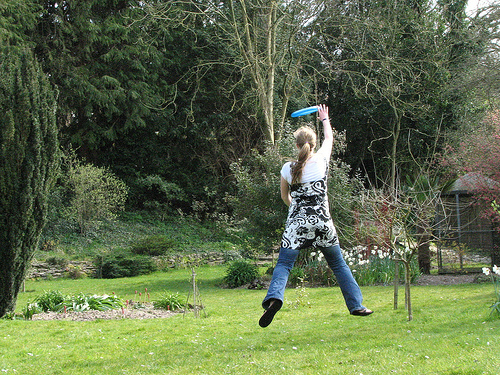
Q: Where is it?
A: This is at the field.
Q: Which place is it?
A: It is a field.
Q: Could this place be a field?
A: Yes, it is a field.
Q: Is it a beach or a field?
A: It is a field.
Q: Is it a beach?
A: No, it is a field.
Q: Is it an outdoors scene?
A: Yes, it is outdoors.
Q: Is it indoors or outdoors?
A: It is outdoors.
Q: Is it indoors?
A: No, it is outdoors.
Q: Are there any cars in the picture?
A: No, there are no cars.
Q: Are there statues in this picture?
A: No, there are no statues.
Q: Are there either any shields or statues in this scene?
A: No, there are no statues or shields.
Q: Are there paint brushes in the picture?
A: No, there are no paint brushes.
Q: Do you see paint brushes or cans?
A: No, there are no paint brushes or cans.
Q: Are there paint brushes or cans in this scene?
A: No, there are no paint brushes or cans.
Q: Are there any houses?
A: No, there are no houses.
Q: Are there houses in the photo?
A: No, there are no houses.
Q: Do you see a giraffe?
A: No, there are no giraffes.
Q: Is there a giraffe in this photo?
A: No, there are no giraffes.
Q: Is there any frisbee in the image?
A: Yes, there is a frisbee.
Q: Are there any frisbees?
A: Yes, there is a frisbee.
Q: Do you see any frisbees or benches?
A: Yes, there is a frisbee.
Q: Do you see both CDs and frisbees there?
A: No, there is a frisbee but no cds.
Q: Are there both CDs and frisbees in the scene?
A: No, there is a frisbee but no cds.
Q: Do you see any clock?
A: No, there are no clocks.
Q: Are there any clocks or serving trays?
A: No, there are no clocks or serving trays.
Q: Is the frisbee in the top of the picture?
A: Yes, the frisbee is in the top of the image.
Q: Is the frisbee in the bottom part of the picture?
A: No, the frisbee is in the top of the image.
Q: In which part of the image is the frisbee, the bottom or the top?
A: The frisbee is in the top of the image.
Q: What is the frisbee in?
A: The frisbee is in the air.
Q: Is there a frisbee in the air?
A: Yes, there is a frisbee in the air.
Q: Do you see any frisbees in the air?
A: Yes, there is a frisbee in the air.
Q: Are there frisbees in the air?
A: Yes, there is a frisbee in the air.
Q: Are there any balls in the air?
A: No, there is a frisbee in the air.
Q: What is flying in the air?
A: The frisbee is flying in the air.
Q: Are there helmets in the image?
A: No, there are no helmets.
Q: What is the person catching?
A: The person is catching a frisbee.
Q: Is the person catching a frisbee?
A: Yes, the person is catching a frisbee.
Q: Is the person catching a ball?
A: No, the person is catching a frisbee.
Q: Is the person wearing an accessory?
A: Yes, the person is wearing an accessory.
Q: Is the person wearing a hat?
A: No, the person is wearing an accessory.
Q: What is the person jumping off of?
A: The person is jumping off the ground.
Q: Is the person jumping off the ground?
A: Yes, the person is jumping off the ground.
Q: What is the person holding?
A: The person is holding the frisbee.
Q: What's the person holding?
A: The person is holding the frisbee.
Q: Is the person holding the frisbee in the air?
A: Yes, the person is holding the frisbee.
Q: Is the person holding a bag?
A: No, the person is holding the frisbee.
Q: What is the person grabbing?
A: The person is grabbing the frisbee.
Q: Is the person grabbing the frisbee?
A: Yes, the person is grabbing the frisbee.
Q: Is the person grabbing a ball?
A: No, the person is grabbing the frisbee.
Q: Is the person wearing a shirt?
A: Yes, the person is wearing a shirt.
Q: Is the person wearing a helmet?
A: No, the person is wearing a shirt.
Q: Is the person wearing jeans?
A: Yes, the person is wearing jeans.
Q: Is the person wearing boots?
A: No, the person is wearing jeans.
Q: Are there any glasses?
A: No, there are no glasses.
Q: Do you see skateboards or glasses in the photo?
A: No, there are no glasses or skateboards.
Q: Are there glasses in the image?
A: No, there are no glasses.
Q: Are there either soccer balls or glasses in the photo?
A: No, there are no glasses or soccer balls.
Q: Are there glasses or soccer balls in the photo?
A: No, there are no glasses or soccer balls.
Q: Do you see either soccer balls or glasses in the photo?
A: No, there are no glasses or soccer balls.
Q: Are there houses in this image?
A: No, there are no houses.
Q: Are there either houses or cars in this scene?
A: No, there are no houses or cars.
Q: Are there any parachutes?
A: No, there are no parachutes.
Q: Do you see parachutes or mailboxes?
A: No, there are no parachutes or mailboxes.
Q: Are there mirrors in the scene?
A: No, there are no mirrors.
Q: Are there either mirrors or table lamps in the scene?
A: No, there are no mirrors or table lamps.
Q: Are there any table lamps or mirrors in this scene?
A: No, there are no mirrors or table lamps.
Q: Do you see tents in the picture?
A: No, there are no tents.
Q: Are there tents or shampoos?
A: No, there are no tents or shampoos.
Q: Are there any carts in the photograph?
A: No, there are no carts.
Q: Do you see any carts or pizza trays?
A: No, there are no carts or pizza trays.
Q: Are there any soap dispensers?
A: No, there are no soap dispensers.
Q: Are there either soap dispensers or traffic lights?
A: No, there are no soap dispensers or traffic lights.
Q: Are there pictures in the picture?
A: No, there are no pictures.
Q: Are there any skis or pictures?
A: No, there are no pictures or skis.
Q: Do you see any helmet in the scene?
A: No, there are no helmets.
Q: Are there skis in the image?
A: No, there are no skis.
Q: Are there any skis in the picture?
A: No, there are no skis.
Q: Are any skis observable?
A: No, there are no skis.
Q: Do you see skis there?
A: No, there are no skis.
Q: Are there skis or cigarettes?
A: No, there are no skis or cigarettes.